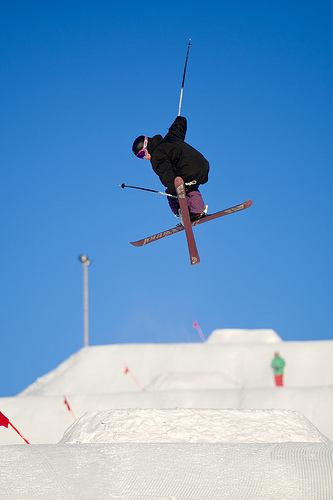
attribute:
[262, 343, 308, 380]
clothing — green, red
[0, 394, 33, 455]
flag — red, stuck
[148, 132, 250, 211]
coat — black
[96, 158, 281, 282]
skis — crossed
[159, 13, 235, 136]
pole — ski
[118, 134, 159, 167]
goggles — ski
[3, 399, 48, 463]
flag — stuck, red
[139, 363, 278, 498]
slopes — white, snow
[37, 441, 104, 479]
snow — stuck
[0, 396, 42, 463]
flag — red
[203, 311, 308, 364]
jump — ski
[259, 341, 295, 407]
person — standing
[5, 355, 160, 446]
flags — three, red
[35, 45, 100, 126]
sky — clear, bright, blue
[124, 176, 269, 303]
skis — crossed, x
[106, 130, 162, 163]
goggles — red, ski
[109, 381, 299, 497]
ramp — groomed, snow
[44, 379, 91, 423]
flag — red, long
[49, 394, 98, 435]
flag — long, red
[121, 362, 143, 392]
flag — red, long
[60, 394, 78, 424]
flag — long, red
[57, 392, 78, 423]
flag — red, long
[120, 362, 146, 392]
flag — long, red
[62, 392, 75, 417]
flag — red, long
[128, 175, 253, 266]
skis — maroon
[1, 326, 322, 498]
snow — white, wavy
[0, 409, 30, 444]
flag — red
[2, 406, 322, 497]
steps — snow covered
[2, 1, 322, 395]
sky — blue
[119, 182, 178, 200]
stick — ski, black, white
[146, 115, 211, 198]
jacket — black